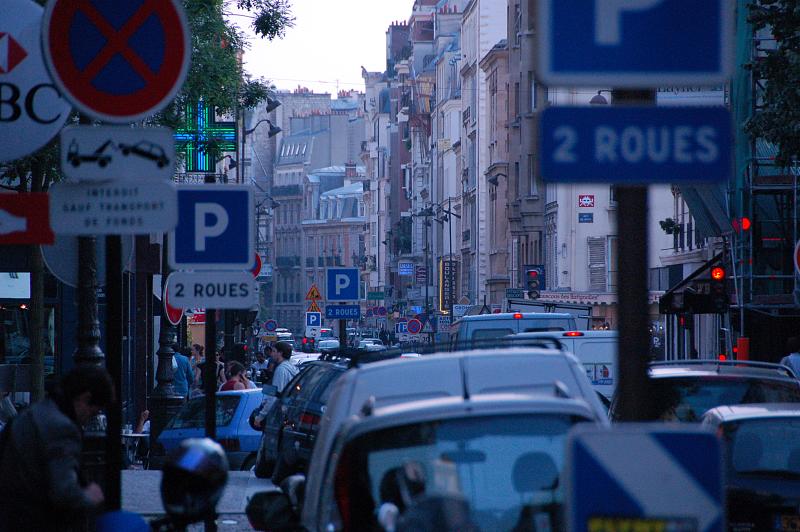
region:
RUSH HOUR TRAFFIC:
[39, 82, 772, 527]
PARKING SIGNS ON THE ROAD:
[162, 179, 387, 307]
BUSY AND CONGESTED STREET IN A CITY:
[250, 157, 786, 530]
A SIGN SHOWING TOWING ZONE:
[44, 111, 185, 236]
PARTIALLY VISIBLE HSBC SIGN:
[0, 7, 61, 136]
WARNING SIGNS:
[304, 279, 326, 313]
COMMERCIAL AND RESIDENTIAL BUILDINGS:
[239, 1, 737, 365]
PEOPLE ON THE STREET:
[148, 330, 303, 394]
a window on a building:
[269, 205, 280, 223]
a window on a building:
[269, 281, 279, 307]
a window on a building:
[271, 281, 289, 295]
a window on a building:
[288, 276, 290, 292]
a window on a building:
[293, 284, 303, 292]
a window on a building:
[285, 312, 293, 334]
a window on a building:
[297, 312, 310, 334]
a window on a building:
[586, 240, 604, 259]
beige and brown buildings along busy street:
[222, 6, 646, 530]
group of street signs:
[0, 0, 270, 531]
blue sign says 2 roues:
[512, 0, 753, 530]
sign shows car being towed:
[48, 0, 184, 530]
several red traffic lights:
[681, 199, 762, 373]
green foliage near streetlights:
[171, 0, 293, 188]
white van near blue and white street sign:
[152, 166, 630, 530]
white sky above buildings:
[196, 0, 404, 338]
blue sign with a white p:
[170, 182, 260, 267]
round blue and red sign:
[41, 6, 204, 126]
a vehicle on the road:
[417, 317, 563, 446]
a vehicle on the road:
[737, 387, 797, 507]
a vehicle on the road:
[474, 312, 552, 353]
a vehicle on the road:
[280, 378, 365, 446]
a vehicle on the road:
[191, 384, 275, 448]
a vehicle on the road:
[278, 318, 331, 356]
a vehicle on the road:
[315, 340, 355, 357]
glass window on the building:
[293, 194, 302, 220]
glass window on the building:
[288, 196, 292, 223]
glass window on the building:
[336, 227, 344, 252]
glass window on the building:
[344, 192, 356, 212]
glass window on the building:
[296, 141, 298, 151]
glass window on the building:
[292, 136, 295, 154]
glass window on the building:
[280, 137, 284, 154]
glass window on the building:
[306, 228, 314, 260]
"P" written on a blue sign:
[158, 173, 263, 275]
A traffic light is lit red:
[697, 242, 741, 323]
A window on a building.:
[295, 312, 305, 333]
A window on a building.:
[285, 309, 295, 327]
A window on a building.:
[279, 307, 287, 325]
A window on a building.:
[277, 270, 279, 297]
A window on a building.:
[271, 205, 282, 227]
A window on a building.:
[337, 234, 347, 260]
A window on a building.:
[585, 238, 605, 256]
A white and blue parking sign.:
[167, 175, 260, 272]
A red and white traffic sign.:
[39, 0, 195, 124]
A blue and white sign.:
[526, 101, 746, 182]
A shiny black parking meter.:
[156, 435, 231, 528]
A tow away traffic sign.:
[57, 124, 183, 180]